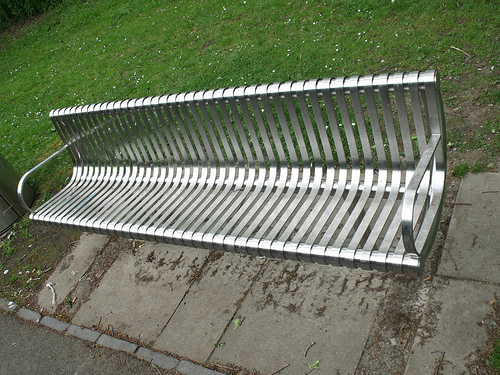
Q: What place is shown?
A: It is a park.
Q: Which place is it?
A: It is a park.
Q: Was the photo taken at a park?
A: Yes, it was taken in a park.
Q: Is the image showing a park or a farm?
A: It is showing a park.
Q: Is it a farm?
A: No, it is a park.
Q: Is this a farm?
A: No, it is a park.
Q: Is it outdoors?
A: Yes, it is outdoors.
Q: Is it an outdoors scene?
A: Yes, it is outdoors.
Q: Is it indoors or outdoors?
A: It is outdoors.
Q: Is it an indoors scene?
A: No, it is outdoors.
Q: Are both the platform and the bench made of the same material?
A: No, the platform is made of concrete and the bench is made of metal.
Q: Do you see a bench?
A: Yes, there is a bench.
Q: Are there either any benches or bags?
A: Yes, there is a bench.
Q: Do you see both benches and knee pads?
A: No, there is a bench but no knee pads.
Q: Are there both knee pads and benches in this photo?
A: No, there is a bench but no knee pads.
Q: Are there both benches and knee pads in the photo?
A: No, there is a bench but no knee pads.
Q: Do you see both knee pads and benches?
A: No, there is a bench but no knee pads.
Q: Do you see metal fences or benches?
A: Yes, there is a metal bench.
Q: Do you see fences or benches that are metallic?
A: Yes, the bench is metallic.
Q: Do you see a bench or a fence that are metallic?
A: Yes, the bench is metallic.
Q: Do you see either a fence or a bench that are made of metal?
A: Yes, the bench is made of metal.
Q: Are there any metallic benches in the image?
A: Yes, there is a metal bench.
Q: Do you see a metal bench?
A: Yes, there is a metal bench.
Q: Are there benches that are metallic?
A: Yes, there is a bench that is metallic.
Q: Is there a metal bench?
A: Yes, there is a bench that is made of metal.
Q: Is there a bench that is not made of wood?
A: Yes, there is a bench that is made of metal.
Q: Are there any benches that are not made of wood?
A: Yes, there is a bench that is made of metal.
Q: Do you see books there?
A: No, there are no books.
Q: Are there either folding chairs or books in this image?
A: No, there are no books or folding chairs.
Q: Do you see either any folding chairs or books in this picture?
A: No, there are no books or folding chairs.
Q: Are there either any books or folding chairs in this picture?
A: No, there are no books or folding chairs.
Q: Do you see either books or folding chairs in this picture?
A: No, there are no books or folding chairs.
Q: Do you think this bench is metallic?
A: Yes, the bench is metallic.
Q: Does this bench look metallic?
A: Yes, the bench is metallic.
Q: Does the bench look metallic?
A: Yes, the bench is metallic.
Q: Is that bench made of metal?
A: Yes, the bench is made of metal.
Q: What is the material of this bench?
A: The bench is made of metal.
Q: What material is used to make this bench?
A: The bench is made of metal.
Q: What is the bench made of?
A: The bench is made of metal.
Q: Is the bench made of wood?
A: No, the bench is made of metal.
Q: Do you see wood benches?
A: No, there is a bench but it is made of metal.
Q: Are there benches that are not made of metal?
A: No, there is a bench but it is made of metal.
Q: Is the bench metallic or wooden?
A: The bench is metallic.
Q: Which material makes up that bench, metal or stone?
A: The bench is made of metal.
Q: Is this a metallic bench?
A: Yes, this is a metallic bench.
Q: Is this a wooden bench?
A: No, this is a metallic bench.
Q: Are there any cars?
A: No, there are no cars.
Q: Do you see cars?
A: No, there are no cars.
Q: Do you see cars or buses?
A: No, there are no cars or buses.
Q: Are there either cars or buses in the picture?
A: No, there are no cars or buses.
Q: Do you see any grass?
A: Yes, there is grass.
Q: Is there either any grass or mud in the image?
A: Yes, there is grass.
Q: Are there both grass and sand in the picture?
A: No, there is grass but no sand.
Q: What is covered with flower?
A: The grass is covered with flower.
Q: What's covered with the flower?
A: The grass is covered with flower.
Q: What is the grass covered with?
A: The grass is covered with flower.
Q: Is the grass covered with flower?
A: Yes, the grass is covered with flower.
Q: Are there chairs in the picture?
A: No, there are no chairs.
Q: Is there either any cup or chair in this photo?
A: No, there are no chairs or cups.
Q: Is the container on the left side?
A: Yes, the container is on the left of the image.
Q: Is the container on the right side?
A: No, the container is on the left of the image.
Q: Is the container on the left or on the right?
A: The container is on the left of the image.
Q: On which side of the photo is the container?
A: The container is on the left of the image.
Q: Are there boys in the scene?
A: No, there are no boys.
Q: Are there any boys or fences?
A: No, there are no boys or fences.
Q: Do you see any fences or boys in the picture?
A: No, there are no boys or fences.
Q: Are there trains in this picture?
A: No, there are no trains.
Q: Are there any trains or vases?
A: No, there are no trains or vases.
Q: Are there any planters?
A: No, there are no planters.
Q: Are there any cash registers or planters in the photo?
A: No, there are no planters or cash registers.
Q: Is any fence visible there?
A: No, there are no fences.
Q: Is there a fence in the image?
A: No, there are no fences.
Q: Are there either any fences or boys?
A: No, there are no fences or boys.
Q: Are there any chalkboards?
A: No, there are no chalkboards.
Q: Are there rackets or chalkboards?
A: No, there are no chalkboards or rackets.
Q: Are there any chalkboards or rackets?
A: No, there are no chalkboards or rackets.